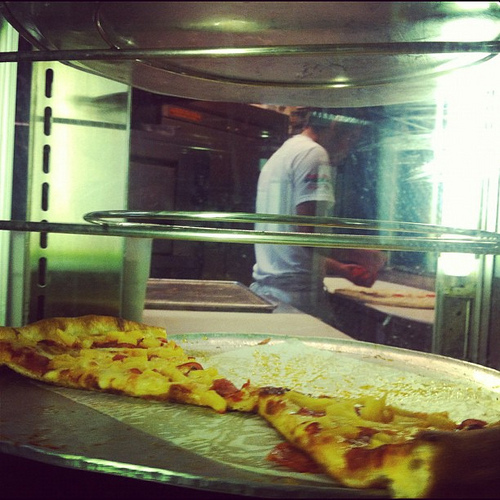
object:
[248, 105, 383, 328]
man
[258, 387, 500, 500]
pizza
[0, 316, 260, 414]
pizza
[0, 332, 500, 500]
tray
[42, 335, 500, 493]
paper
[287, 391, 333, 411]
pineapple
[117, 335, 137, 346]
pineapple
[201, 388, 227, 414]
pineapple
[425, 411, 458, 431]
pineapple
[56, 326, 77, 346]
pineapple